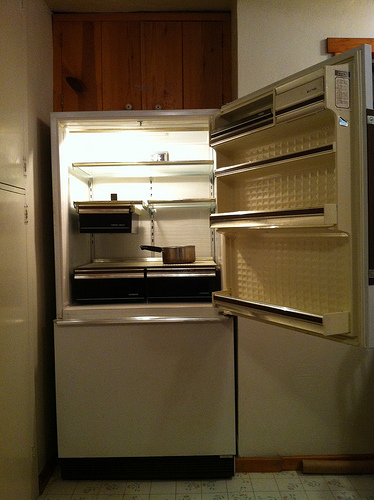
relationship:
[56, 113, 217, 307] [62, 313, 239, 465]
refrigerator and freezer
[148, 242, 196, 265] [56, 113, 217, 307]
pan in refrigerator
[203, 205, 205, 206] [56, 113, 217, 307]
drawers in refrigerator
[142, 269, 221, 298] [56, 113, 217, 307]
drawer in refrigerator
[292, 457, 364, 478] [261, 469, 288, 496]
tube on floor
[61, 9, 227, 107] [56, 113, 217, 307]
cabinets above refrigerator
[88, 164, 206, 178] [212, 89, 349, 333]
shelf of door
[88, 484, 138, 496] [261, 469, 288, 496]
flower on floor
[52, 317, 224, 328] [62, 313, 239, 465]
handle on freezer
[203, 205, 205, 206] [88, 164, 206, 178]
drawers on shelf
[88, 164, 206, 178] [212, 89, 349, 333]
shelf in door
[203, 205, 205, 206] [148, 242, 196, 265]
drawers under pan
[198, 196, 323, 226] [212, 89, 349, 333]
hinges on door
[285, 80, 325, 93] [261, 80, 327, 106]
butter written on compartment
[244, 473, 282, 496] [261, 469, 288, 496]
tiles on floor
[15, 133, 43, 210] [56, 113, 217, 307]
trim on refrigerator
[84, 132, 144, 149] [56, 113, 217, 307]
light in refrigerator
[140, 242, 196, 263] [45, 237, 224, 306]
pan inside fridge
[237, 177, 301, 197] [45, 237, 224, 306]
wall behind fridge